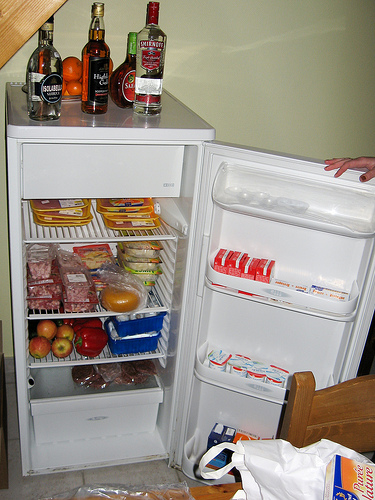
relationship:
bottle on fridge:
[27, 14, 63, 122] [6, 81, 373, 477]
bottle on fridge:
[80, 2, 111, 115] [6, 81, 373, 477]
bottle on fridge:
[110, 31, 138, 109] [6, 81, 373, 477]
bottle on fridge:
[133, 1, 167, 116] [6, 81, 373, 477]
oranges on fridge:
[22, 56, 114, 101] [6, 81, 373, 477]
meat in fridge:
[31, 199, 95, 227] [6, 81, 373, 477]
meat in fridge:
[96, 197, 160, 230] [6, 81, 373, 477]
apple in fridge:
[29, 336, 52, 359] [6, 81, 373, 477]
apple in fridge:
[51, 337, 74, 359] [6, 81, 373, 477]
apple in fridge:
[37, 320, 60, 340] [6, 81, 373, 477]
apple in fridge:
[57, 324, 75, 342] [6, 81, 373, 477]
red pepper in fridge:
[74, 327, 110, 358] [6, 81, 373, 477]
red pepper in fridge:
[73, 317, 103, 333] [6, 81, 373, 477]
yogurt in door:
[208, 347, 233, 372] [168, 138, 374, 486]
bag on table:
[199, 439, 375, 500] [86, 482, 244, 499]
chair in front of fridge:
[278, 370, 374, 454] [6, 81, 373, 477]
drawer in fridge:
[29, 365, 164, 443] [6, 81, 373, 477]